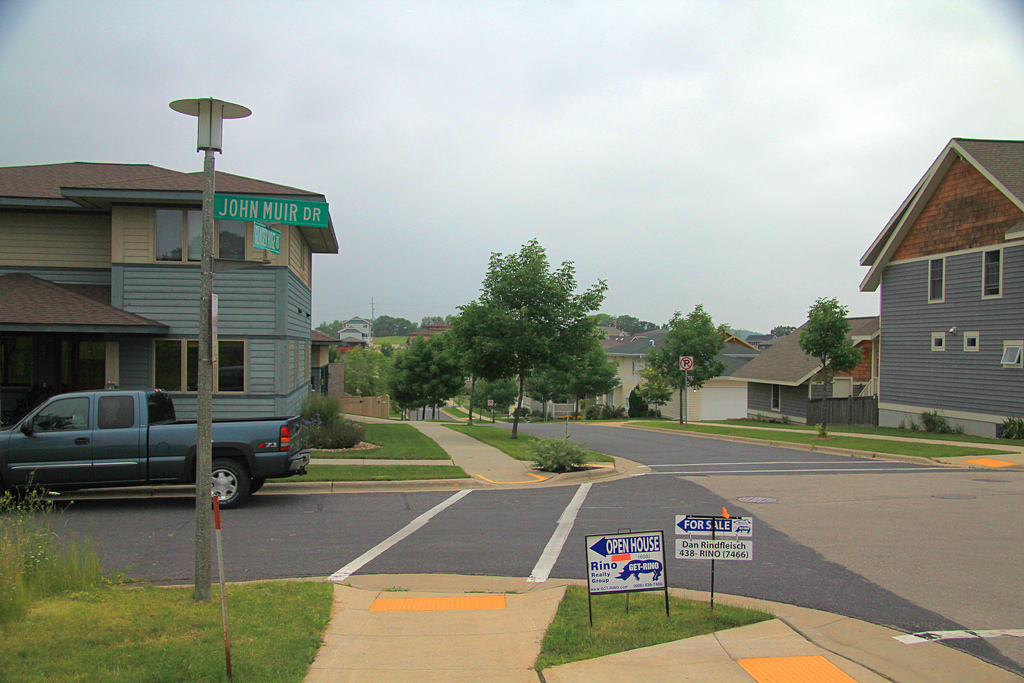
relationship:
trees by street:
[427, 279, 652, 431] [567, 391, 976, 616]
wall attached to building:
[336, 387, 393, 424] [305, 325, 349, 410]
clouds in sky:
[11, 9, 992, 323] [6, 5, 992, 330]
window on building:
[218, 336, 244, 388] [1, 161, 339, 438]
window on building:
[187, 338, 198, 395] [1, 161, 339, 438]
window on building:
[155, 345, 186, 393] [1, 161, 339, 438]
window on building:
[217, 215, 246, 261] [1, 161, 339, 438]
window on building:
[161, 211, 183, 257] [1, 161, 339, 438]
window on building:
[980, 249, 1002, 295] [852, 137, 1021, 444]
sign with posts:
[585, 528, 670, 628] [583, 589, 672, 620]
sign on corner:
[675, 507, 753, 612] [550, 470, 1021, 680]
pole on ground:
[213, 496, 233, 682] [3, 578, 338, 680]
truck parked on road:
[6, 386, 307, 507] [0, 406, 1024, 677]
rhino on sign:
[621, 556, 663, 580] [583, 526, 674, 626]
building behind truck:
[0, 161, 340, 432] [6, 386, 307, 507]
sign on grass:
[583, 526, 674, 626] [528, 582, 779, 672]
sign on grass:
[671, 507, 754, 564] [533, 580, 775, 667]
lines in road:
[326, 478, 590, 587] [0, 406, 1024, 677]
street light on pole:
[172, 96, 255, 155] [200, 152, 214, 591]